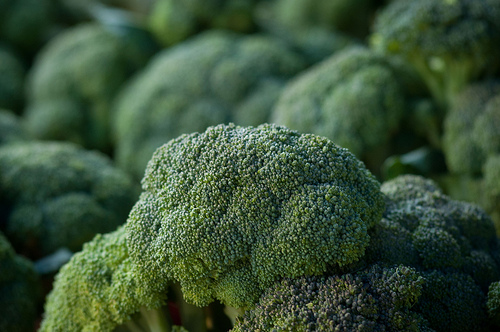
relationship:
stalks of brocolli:
[137, 298, 172, 332] [41, 226, 212, 328]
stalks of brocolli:
[137, 303, 171, 330] [41, 226, 212, 328]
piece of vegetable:
[127, 121, 380, 327] [4, 6, 497, 328]